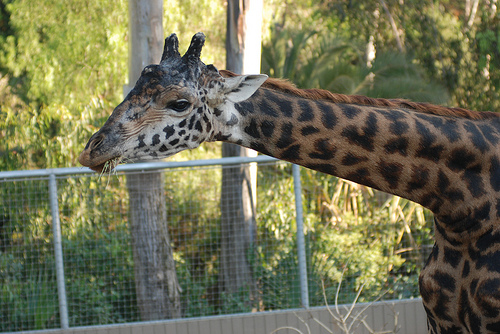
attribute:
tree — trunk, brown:
[122, 32, 302, 302]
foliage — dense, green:
[309, 37, 444, 83]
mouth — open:
[73, 140, 130, 178]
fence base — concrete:
[1, 298, 426, 332]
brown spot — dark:
[165, 133, 182, 156]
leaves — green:
[6, 6, 130, 105]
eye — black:
[166, 95, 197, 114]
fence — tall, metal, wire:
[8, 147, 429, 332]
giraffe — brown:
[97, 51, 493, 329]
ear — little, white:
[215, 65, 278, 104]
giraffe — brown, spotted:
[115, 51, 492, 311]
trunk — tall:
[67, 31, 224, 225]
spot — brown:
[339, 110, 382, 154]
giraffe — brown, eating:
[75, 32, 497, 332]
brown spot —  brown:
[444, 145, 477, 177]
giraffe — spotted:
[58, 31, 491, 271]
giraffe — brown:
[43, 19, 498, 286]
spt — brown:
[171, 114, 189, 130]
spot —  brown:
[317, 107, 343, 142]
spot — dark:
[177, 116, 191, 133]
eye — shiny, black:
[165, 97, 192, 113]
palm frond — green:
[360, 79, 446, 106]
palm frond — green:
[348, 51, 418, 101]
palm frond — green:
[318, 60, 359, 90]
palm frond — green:
[293, 38, 356, 87]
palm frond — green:
[283, 27, 315, 79]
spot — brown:
[308, 136, 339, 162]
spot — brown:
[296, 97, 316, 125]